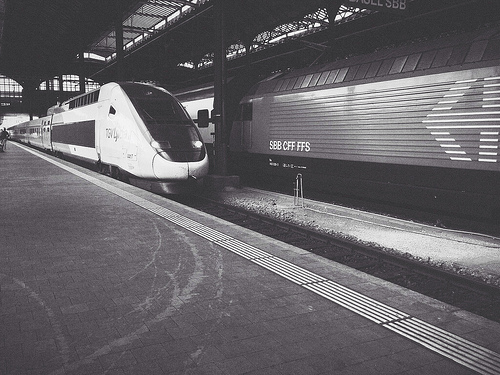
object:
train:
[7, 78, 212, 198]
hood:
[117, 83, 207, 166]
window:
[50, 119, 97, 151]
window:
[117, 83, 207, 161]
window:
[91, 89, 99, 105]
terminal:
[0, 0, 499, 374]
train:
[170, 25, 499, 219]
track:
[164, 195, 499, 321]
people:
[0, 124, 8, 155]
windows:
[58, 74, 79, 90]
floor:
[0, 140, 499, 373]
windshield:
[117, 83, 207, 163]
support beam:
[202, 11, 240, 192]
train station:
[1, 0, 499, 373]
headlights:
[150, 140, 173, 151]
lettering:
[302, 141, 312, 152]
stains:
[92, 228, 207, 372]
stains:
[113, 217, 164, 287]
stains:
[182, 300, 234, 368]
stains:
[0, 272, 69, 371]